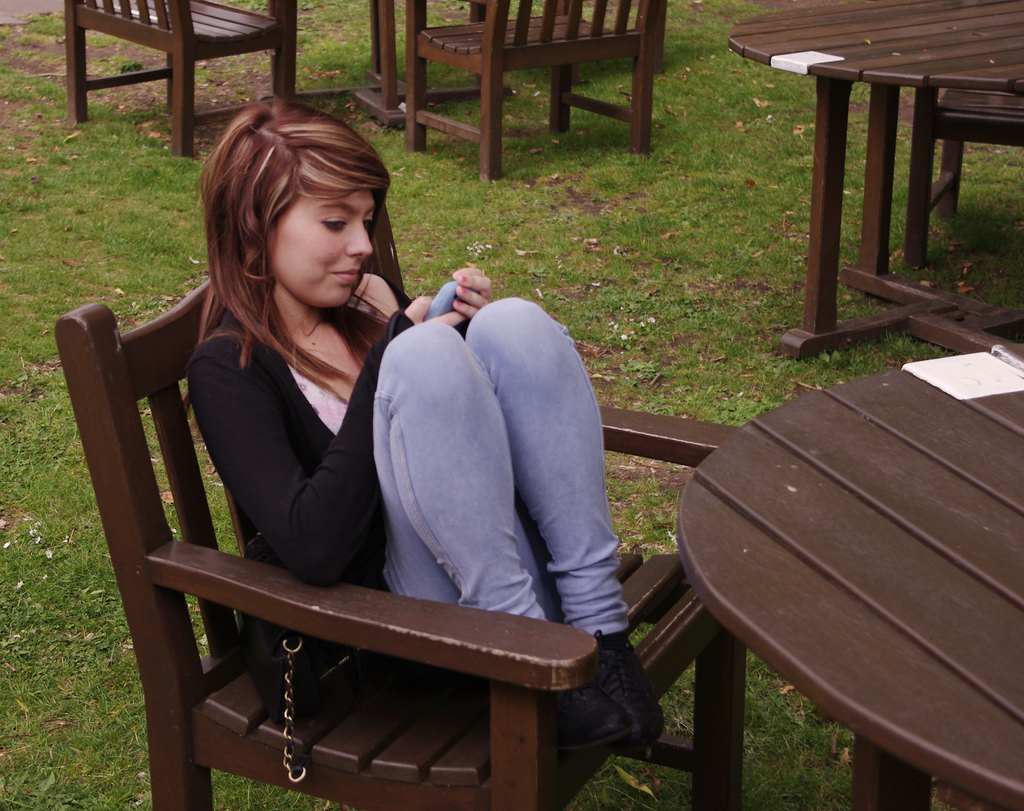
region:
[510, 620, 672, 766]
Girl wearing shoes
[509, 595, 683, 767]
Girl is wearing shoes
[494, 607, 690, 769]
Girl wearing black shoes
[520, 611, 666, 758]
Girl is wearing black shoes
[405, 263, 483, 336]
Girl holding a phone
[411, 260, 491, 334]
Girl is holding a phone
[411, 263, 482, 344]
Girl holding a cell phone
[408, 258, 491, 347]
Girl is holding a cell phone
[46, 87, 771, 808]
Girl is sitting on a chair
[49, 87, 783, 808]
Girl is sitting on a wooden chair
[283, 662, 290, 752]
A shiny chain hanging down on the side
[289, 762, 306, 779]
The ring of a chain touching a chair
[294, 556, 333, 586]
Elbow of girl resting on the arm-rest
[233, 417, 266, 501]
Arm of a girl covered by a sweater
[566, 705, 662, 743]
The shoes of a girl resting on the chair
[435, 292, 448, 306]
A phone in the hands of a girl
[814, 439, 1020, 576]
The painted surface of a table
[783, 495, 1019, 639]
The wooden surface of a table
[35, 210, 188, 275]
A patch of green grass on the ground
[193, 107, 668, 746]
girl is sitting down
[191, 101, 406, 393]
brown and blonde hair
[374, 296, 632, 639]
the pants are gray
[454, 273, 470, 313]
finger nails are pink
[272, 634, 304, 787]
chain is hanging down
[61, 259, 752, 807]
the chair is brown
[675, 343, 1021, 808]
the table is brown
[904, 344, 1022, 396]
paper on the table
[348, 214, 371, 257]
nose of a girl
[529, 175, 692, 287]
leaves on the ground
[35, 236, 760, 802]
wooden chair on the grass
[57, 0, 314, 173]
wooden chair on the grass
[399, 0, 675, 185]
wooden chair on the grass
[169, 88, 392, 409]
girl with long brown hair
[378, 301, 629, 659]
pair of denim jeggings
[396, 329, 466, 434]
knee of a girl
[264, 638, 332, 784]
chain on a chair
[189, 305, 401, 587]
arm of a girl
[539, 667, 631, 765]
a small black shoe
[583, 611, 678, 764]
a small black shoe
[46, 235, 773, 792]
a brown wooden chair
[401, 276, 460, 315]
a small blue cell phone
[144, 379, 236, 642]
chair has a wood panel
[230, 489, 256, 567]
chair has a wood panel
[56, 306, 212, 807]
chair has a wood panel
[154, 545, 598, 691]
chair has a wood panel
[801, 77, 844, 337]
chair has a wood panel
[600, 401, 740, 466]
chair has a wood panel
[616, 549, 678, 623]
chair has a wood panel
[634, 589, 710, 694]
chair has a wood panel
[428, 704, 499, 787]
chair has a wood panel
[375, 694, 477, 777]
chair has a wood panel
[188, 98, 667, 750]
Brown haired girl sitting in a chair.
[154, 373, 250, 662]
A small wooden bar.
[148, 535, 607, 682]
A small wooden bar.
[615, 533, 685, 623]
A small wooden bar.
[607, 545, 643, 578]
A small wooden bar.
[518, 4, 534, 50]
A small wooden bar.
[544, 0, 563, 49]
A small wooden bar.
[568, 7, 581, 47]
A small wooden bar.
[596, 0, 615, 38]
A small wooden bar.